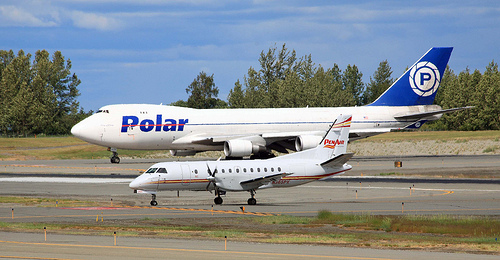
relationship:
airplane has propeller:
[126, 112, 356, 207] [206, 163, 220, 191]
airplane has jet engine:
[69, 45, 479, 165] [223, 138, 268, 158]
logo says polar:
[120, 113, 190, 133] [120, 112, 189, 132]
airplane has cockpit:
[126, 112, 356, 207] [144, 160, 183, 179]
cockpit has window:
[144, 160, 183, 179] [145, 166, 159, 174]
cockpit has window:
[144, 160, 183, 179] [157, 166, 168, 174]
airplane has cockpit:
[69, 45, 479, 165] [95, 102, 117, 119]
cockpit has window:
[95, 102, 117, 119] [101, 108, 109, 113]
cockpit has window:
[95, 102, 117, 119] [95, 108, 103, 113]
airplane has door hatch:
[126, 112, 356, 207] [179, 162, 193, 188]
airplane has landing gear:
[69, 45, 479, 165] [108, 150, 122, 164]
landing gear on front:
[108, 150, 122, 164] [71, 102, 198, 163]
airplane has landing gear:
[126, 112, 356, 207] [149, 190, 159, 207]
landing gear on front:
[149, 190, 159, 207] [128, 160, 193, 207]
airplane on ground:
[69, 45, 479, 165] [1, 129, 500, 258]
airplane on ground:
[126, 112, 356, 207] [1, 129, 500, 258]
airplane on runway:
[69, 45, 479, 165] [1, 153, 499, 176]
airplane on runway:
[126, 112, 356, 207] [0, 176, 499, 223]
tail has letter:
[361, 46, 455, 106] [419, 71, 432, 86]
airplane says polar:
[69, 45, 479, 165] [120, 112, 189, 132]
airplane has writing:
[126, 112, 356, 207] [323, 138, 346, 146]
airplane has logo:
[69, 45, 479, 165] [120, 113, 190, 133]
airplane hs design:
[69, 45, 479, 165] [409, 60, 442, 96]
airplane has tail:
[69, 45, 479, 165] [361, 46, 455, 106]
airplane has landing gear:
[126, 112, 356, 207] [215, 187, 257, 206]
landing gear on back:
[215, 187, 257, 206] [213, 112, 354, 205]